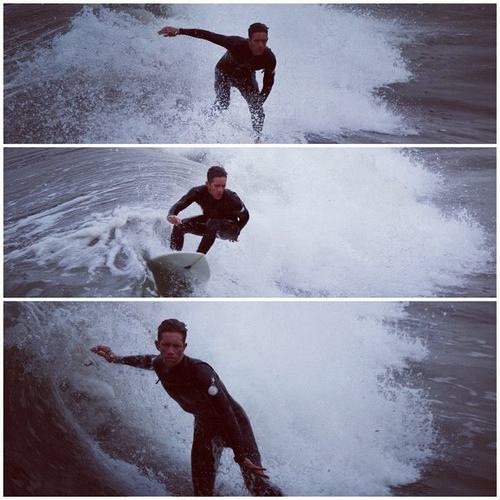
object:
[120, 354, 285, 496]
black suit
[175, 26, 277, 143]
suit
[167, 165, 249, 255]
man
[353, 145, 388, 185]
ground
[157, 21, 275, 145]
man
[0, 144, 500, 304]
wave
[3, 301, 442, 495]
wave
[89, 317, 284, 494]
man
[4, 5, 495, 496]
ocean water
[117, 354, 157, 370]
arm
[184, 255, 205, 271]
design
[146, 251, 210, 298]
surf board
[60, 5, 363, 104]
water spray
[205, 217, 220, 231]
knee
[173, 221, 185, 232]
knee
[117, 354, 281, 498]
suit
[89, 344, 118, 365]
right hand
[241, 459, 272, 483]
left hand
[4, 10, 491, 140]
wave